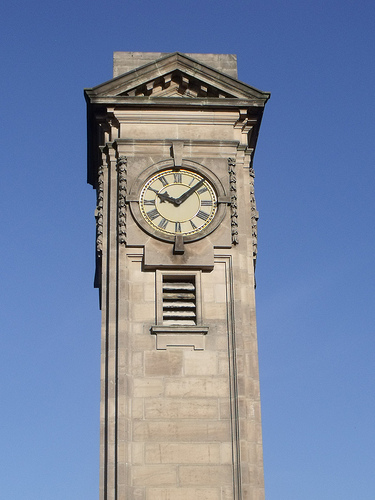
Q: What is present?
A: A tower.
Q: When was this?
A: Daytime.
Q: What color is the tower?
A: Grey.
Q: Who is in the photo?
A: Nobody.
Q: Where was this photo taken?
A: In front of a clock tower.